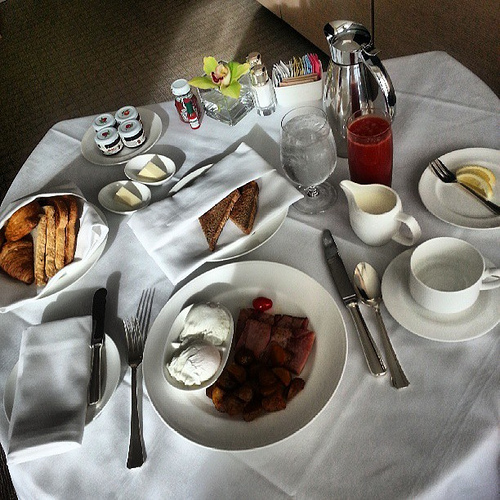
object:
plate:
[417, 145, 499, 230]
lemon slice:
[454, 165, 493, 200]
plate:
[142, 254, 350, 451]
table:
[0, 48, 500, 497]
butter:
[137, 161, 166, 180]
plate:
[123, 153, 176, 187]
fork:
[123, 287, 153, 470]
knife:
[87, 286, 106, 405]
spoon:
[352, 260, 411, 388]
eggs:
[167, 304, 232, 385]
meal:
[0, 20, 497, 459]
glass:
[347, 111, 394, 188]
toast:
[32, 196, 84, 288]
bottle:
[171, 78, 200, 122]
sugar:
[270, 60, 292, 85]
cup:
[408, 235, 499, 315]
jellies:
[92, 103, 145, 156]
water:
[281, 118, 338, 187]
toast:
[201, 178, 262, 251]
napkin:
[127, 141, 304, 287]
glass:
[281, 104, 334, 210]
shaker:
[247, 74, 279, 117]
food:
[206, 296, 317, 422]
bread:
[5, 200, 44, 242]